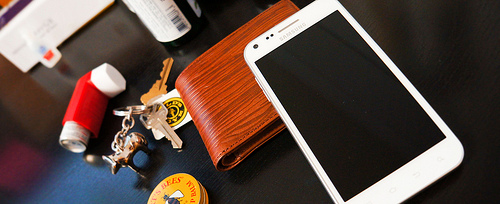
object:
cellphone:
[230, 0, 473, 204]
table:
[0, 2, 499, 204]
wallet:
[167, 0, 314, 174]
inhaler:
[50, 57, 131, 156]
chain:
[102, 98, 153, 155]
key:
[137, 53, 179, 109]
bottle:
[108, 0, 212, 51]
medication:
[120, 0, 201, 45]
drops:
[12, 23, 68, 73]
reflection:
[1, 133, 65, 199]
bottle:
[15, 28, 70, 74]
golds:
[134, 101, 186, 150]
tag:
[146, 95, 195, 129]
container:
[136, 172, 223, 204]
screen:
[254, 9, 447, 204]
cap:
[80, 58, 137, 97]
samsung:
[273, 16, 316, 43]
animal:
[93, 126, 163, 187]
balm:
[140, 172, 216, 203]